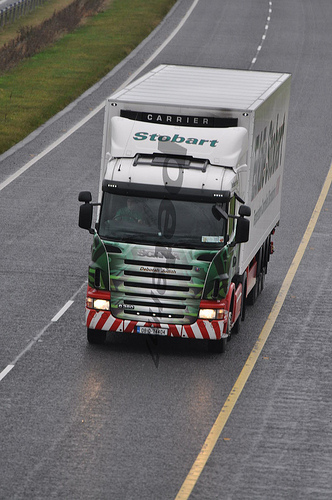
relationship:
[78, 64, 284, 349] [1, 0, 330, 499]
truck on road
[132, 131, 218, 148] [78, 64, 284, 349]
print on truck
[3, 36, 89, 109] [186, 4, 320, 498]
grass on road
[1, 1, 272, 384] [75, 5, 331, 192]
lines on road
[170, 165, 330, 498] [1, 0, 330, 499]
line on road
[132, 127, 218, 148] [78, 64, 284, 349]
print on truck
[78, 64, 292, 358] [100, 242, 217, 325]
truck has grill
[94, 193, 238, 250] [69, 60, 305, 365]
window on truck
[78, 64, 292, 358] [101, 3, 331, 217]
truck on road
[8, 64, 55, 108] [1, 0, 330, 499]
grass near road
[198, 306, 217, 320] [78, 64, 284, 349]
headlight on truck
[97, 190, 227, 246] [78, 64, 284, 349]
windshield on truck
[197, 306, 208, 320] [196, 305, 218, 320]
part of light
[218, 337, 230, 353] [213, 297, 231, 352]
edge of wheel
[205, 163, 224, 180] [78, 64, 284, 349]
part of truck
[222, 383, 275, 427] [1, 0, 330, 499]
edge of road